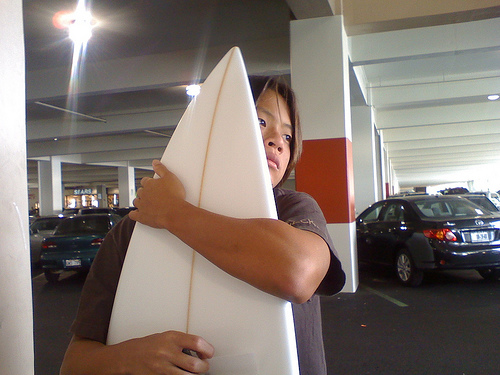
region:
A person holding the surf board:
[113, 40, 312, 372]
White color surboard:
[101, 41, 291, 373]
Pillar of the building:
[288, 18, 356, 290]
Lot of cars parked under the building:
[42, 170, 492, 314]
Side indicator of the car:
[422, 224, 462, 241]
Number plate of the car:
[466, 229, 498, 246]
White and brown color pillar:
[287, 21, 369, 292]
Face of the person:
[257, 84, 302, 182]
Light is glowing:
[39, 8, 138, 63]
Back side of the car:
[423, 212, 498, 267]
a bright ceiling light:
[63, 14, 98, 49]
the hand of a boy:
[121, 161, 183, 228]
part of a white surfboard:
[100, 44, 300, 374]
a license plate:
[472, 230, 492, 242]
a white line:
[361, 276, 409, 309]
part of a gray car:
[357, 185, 498, 280]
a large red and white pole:
[290, 17, 357, 293]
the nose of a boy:
[262, 120, 289, 154]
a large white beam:
[346, 18, 498, 68]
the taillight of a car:
[38, 238, 55, 250]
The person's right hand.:
[130, 155, 183, 230]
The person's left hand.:
[135, 331, 221, 373]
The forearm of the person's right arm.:
[182, 195, 276, 282]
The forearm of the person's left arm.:
[80, 334, 126, 374]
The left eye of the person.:
[255, 114, 268, 130]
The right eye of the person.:
[280, 130, 292, 142]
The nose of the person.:
[266, 128, 283, 150]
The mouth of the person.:
[264, 148, 279, 170]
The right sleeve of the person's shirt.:
[278, 188, 344, 300]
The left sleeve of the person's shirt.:
[80, 205, 130, 325]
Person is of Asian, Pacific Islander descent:
[235, 72, 308, 193]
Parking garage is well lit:
[50, 4, 205, 101]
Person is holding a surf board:
[142, 65, 272, 372]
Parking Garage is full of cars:
[35, 212, 498, 290]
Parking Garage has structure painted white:
[287, 31, 354, 287]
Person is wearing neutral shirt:
[270, 192, 335, 368]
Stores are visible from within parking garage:
[30, 187, 136, 207]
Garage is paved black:
[15, 275, 490, 365]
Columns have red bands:
[289, 142, 353, 226]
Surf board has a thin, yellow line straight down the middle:
[193, 47, 248, 372]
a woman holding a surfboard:
[56, 73, 346, 374]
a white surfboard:
[103, 44, 299, 374]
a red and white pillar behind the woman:
[286, 12, 359, 295]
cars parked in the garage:
[22, 184, 499, 289]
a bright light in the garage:
[59, 5, 99, 48]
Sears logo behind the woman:
[73, 187, 92, 195]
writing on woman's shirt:
[282, 217, 319, 231]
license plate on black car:
[469, 232, 491, 242]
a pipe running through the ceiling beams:
[33, 98, 173, 143]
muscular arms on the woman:
[58, 158, 329, 373]